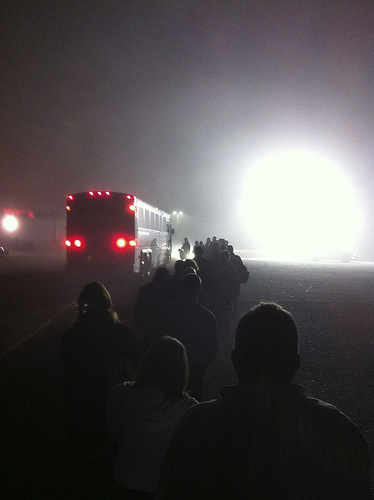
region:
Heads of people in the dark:
[183, 237, 241, 266]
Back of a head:
[132, 337, 196, 398]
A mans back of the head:
[226, 302, 301, 388]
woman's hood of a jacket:
[110, 378, 202, 436]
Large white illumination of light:
[242, 147, 370, 262]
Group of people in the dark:
[184, 234, 248, 323]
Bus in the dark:
[64, 190, 172, 283]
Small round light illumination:
[2, 207, 19, 236]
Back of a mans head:
[231, 298, 302, 386]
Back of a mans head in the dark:
[182, 274, 202, 295]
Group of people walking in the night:
[179, 237, 242, 313]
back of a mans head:
[228, 301, 303, 388]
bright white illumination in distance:
[244, 139, 366, 271]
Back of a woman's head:
[137, 334, 192, 405]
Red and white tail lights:
[61, 235, 82, 251]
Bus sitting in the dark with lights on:
[63, 190, 177, 278]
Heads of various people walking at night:
[196, 238, 233, 259]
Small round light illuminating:
[2, 214, 20, 234]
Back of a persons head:
[75, 282, 116, 323]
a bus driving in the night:
[59, 187, 169, 276]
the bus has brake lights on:
[63, 187, 170, 278]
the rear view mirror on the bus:
[165, 212, 176, 259]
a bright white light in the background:
[230, 144, 366, 258]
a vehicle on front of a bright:
[266, 229, 356, 260]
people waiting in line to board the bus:
[11, 235, 370, 469]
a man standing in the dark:
[165, 300, 368, 496]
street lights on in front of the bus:
[157, 202, 187, 259]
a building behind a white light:
[0, 202, 64, 260]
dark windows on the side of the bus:
[133, 205, 172, 235]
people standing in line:
[149, 219, 288, 494]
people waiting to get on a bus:
[54, 198, 187, 286]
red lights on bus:
[52, 188, 164, 268]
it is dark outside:
[10, 250, 367, 413]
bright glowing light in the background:
[223, 155, 371, 281]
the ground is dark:
[255, 247, 360, 482]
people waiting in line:
[143, 213, 310, 458]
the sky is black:
[20, 74, 329, 181]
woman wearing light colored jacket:
[83, 377, 203, 489]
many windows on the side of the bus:
[133, 207, 178, 235]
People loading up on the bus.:
[107, 158, 318, 388]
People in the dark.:
[37, 319, 223, 433]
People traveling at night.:
[52, 165, 251, 370]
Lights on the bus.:
[37, 162, 168, 322]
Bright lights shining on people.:
[178, 89, 373, 249]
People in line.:
[98, 218, 281, 433]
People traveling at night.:
[123, 171, 304, 393]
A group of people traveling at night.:
[154, 170, 328, 403]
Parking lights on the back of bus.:
[111, 218, 144, 265]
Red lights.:
[74, 160, 169, 342]